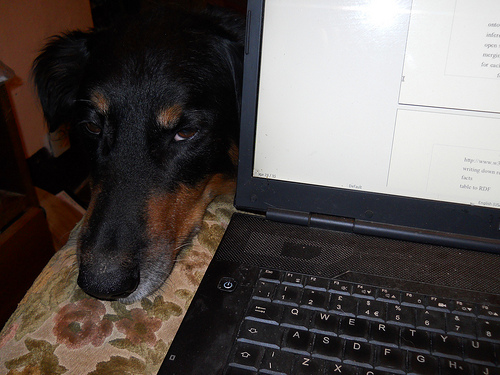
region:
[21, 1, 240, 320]
face of a dog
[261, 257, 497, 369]
buttons on a keyboard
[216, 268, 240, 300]
power button on keyboard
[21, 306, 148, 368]
pattern on a chair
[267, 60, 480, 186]
screen of a laptop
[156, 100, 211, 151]
left eye of a dog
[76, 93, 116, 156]
right eye of a dog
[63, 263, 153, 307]
nose of a dog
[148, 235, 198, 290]
whiskers on dog's nose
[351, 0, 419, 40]
light shining on screen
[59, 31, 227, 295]
the dog looks bored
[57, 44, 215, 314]
the dog is black and brown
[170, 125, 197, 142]
the dog has brown eyes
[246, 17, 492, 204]
the laptop is on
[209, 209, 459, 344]
the laptop is dusty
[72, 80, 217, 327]
head on the arm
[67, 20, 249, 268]
the dog is fuzzy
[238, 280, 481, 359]
the keys are dirty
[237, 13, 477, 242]
the screen is on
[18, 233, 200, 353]
The couch is floral patterned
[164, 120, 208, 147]
Eye of watching dog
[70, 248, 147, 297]
Nose of watching dog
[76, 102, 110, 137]
Eye of watching dog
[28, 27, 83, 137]
Ear of watching dog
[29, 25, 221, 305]
Head of watching dog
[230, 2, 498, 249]
Viewing screen for laptop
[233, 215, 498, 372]
Part of laptop keyboard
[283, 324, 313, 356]
A key on keyboard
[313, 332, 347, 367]
S key on keyboard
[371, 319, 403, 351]
R key on keyboard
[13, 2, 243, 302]
A black and brown dog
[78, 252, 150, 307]
The black nose of the dog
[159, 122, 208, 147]
The right eye of the dog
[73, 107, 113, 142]
The left eye of the dog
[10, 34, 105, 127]
The right ear of the dog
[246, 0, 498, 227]
The computer monitor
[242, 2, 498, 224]
The screen of the monitor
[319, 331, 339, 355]
The letter S on the keyboard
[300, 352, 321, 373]
The letter Z on the keyboard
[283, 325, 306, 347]
The letter A on the keyboard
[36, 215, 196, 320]
a nose of a dog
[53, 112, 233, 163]
eyes of a dog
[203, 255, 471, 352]
keys on a key board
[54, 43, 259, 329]
a dogs head on a chair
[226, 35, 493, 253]
screen of a key board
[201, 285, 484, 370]
black keys on a key board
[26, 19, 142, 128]
a dogs black ear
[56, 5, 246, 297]
a black and brown dog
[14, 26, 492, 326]
a laptop near a dog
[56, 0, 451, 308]
a dog near a laptop